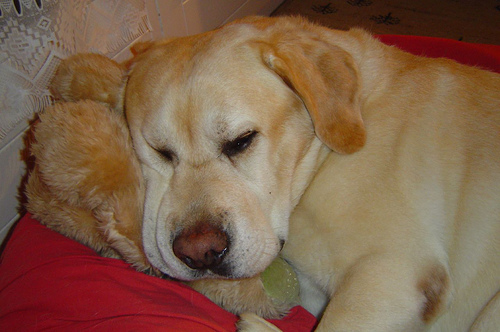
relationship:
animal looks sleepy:
[123, 14, 499, 332] [142, 99, 309, 332]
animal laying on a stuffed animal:
[123, 14, 499, 332] [69, 167, 136, 311]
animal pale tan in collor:
[123, 14, 499, 332] [178, 132, 414, 287]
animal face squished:
[123, 14, 499, 332] [129, 114, 395, 332]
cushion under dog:
[0, 212, 320, 332] [165, 194, 414, 309]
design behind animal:
[6, 0, 59, 76] [123, 14, 499, 332]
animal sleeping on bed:
[123, 14, 499, 332] [11, 207, 246, 329]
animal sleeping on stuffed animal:
[123, 14, 499, 332] [13, 46, 153, 262]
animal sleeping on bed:
[123, 14, 499, 332] [8, 219, 191, 328]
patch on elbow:
[424, 259, 454, 329] [342, 229, 464, 329]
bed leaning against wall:
[11, 210, 160, 328] [8, 0, 62, 209]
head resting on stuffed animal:
[125, 16, 369, 284] [21, 49, 167, 270]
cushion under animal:
[13, 219, 162, 328] [123, 14, 499, 332]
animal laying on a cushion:
[123, 14, 499, 332] [11, 220, 191, 329]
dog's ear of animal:
[260, 34, 368, 155] [123, 14, 499, 332]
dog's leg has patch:
[306, 190, 462, 330] [417, 263, 450, 324]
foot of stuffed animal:
[261, 250, 301, 320] [21, 50, 308, 322]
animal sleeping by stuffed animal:
[123, 14, 499, 332] [21, 50, 308, 322]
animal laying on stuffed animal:
[123, 14, 499, 332] [21, 50, 308, 322]